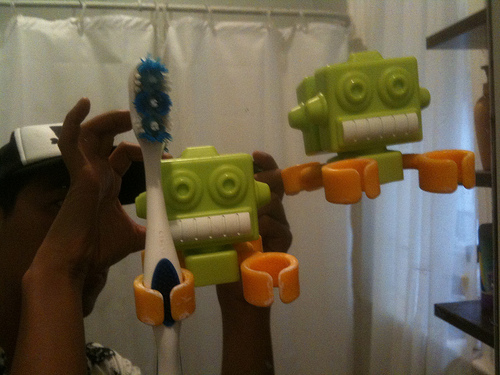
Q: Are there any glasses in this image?
A: No, there are no glasses.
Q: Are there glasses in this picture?
A: No, there are no glasses.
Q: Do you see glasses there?
A: No, there are no glasses.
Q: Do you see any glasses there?
A: No, there are no glasses.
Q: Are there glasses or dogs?
A: No, there are no glasses or dogs.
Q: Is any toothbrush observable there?
A: Yes, there is a toothbrush.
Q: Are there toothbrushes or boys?
A: Yes, there is a toothbrush.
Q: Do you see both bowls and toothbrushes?
A: No, there is a toothbrush but no bowls.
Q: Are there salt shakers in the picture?
A: No, there are no salt shakers.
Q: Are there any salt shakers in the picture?
A: No, there are no salt shakers.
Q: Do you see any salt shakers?
A: No, there are no salt shakers.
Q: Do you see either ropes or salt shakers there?
A: No, there are no salt shakers or ropes.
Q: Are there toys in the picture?
A: Yes, there is a toy.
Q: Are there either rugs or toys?
A: Yes, there is a toy.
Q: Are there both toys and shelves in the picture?
A: Yes, there are both a toy and a shelf.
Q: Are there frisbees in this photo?
A: No, there are no frisbees.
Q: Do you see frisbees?
A: No, there are no frisbees.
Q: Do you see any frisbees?
A: No, there are no frisbees.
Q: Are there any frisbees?
A: No, there are no frisbees.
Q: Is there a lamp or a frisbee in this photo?
A: No, there are no frisbees or lamps.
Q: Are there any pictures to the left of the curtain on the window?
A: No, there is a toy to the left of the curtain.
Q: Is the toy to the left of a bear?
A: No, the toy is to the left of the curtain.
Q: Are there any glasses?
A: No, there are no glasses.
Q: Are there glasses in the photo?
A: No, there are no glasses.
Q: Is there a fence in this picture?
A: No, there are no fences.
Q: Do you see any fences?
A: No, there are no fences.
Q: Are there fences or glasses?
A: No, there are no fences or glasses.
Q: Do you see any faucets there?
A: No, there are no faucets.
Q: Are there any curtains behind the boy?
A: Yes, there is a curtain behind the boy.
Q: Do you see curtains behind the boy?
A: Yes, there is a curtain behind the boy.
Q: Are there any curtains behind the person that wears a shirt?
A: Yes, there is a curtain behind the boy.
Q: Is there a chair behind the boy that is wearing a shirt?
A: No, there is a curtain behind the boy.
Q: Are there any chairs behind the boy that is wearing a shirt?
A: No, there is a curtain behind the boy.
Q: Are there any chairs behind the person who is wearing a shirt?
A: No, there is a curtain behind the boy.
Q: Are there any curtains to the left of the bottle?
A: Yes, there is a curtain to the left of the bottle.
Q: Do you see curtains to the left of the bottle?
A: Yes, there is a curtain to the left of the bottle.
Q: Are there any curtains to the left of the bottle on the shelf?
A: Yes, there is a curtain to the left of the bottle.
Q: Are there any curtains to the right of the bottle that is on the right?
A: No, the curtain is to the left of the bottle.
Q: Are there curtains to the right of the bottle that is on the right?
A: No, the curtain is to the left of the bottle.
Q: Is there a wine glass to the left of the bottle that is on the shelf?
A: No, there is a curtain to the left of the bottle.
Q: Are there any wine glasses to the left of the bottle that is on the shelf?
A: No, there is a curtain to the left of the bottle.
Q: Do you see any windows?
A: Yes, there is a window.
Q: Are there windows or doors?
A: Yes, there is a window.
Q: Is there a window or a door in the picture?
A: Yes, there is a window.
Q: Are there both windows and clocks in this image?
A: No, there is a window but no clocks.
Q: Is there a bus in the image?
A: No, there are no buses.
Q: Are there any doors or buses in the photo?
A: No, there are no buses or doors.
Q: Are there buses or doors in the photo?
A: No, there are no buses or doors.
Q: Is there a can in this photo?
A: Yes, there is a can.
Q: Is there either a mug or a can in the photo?
A: Yes, there is a can.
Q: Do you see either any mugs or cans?
A: Yes, there is a can.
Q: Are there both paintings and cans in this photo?
A: No, there is a can but no paintings.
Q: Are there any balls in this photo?
A: No, there are no balls.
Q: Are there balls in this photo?
A: No, there are no balls.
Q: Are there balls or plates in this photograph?
A: No, there are no balls or plates.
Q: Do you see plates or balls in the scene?
A: No, there are no balls or plates.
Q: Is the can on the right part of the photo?
A: Yes, the can is on the right of the image.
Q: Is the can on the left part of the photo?
A: No, the can is on the right of the image.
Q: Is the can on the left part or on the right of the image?
A: The can is on the right of the image.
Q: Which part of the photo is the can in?
A: The can is on the right of the image.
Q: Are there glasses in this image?
A: No, there are no glasses.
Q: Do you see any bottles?
A: Yes, there is a bottle.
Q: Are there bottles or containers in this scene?
A: Yes, there is a bottle.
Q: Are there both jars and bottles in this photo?
A: No, there is a bottle but no jars.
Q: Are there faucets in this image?
A: No, there are no faucets.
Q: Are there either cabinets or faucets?
A: No, there are no faucets or cabinets.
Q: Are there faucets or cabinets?
A: No, there are no faucets or cabinets.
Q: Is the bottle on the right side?
A: Yes, the bottle is on the right of the image.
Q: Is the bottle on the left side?
A: No, the bottle is on the right of the image.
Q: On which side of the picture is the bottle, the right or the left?
A: The bottle is on the right of the image.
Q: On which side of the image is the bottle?
A: The bottle is on the right of the image.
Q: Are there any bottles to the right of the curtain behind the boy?
A: Yes, there is a bottle to the right of the curtain.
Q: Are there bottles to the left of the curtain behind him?
A: No, the bottle is to the right of the curtain.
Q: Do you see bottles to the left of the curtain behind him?
A: No, the bottle is to the right of the curtain.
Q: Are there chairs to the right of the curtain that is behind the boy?
A: No, there is a bottle to the right of the curtain.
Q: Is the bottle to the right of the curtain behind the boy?
A: Yes, the bottle is to the right of the curtain.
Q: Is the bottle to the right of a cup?
A: No, the bottle is to the right of the curtain.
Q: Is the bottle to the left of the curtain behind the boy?
A: No, the bottle is to the right of the curtain.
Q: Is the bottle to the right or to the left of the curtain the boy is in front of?
A: The bottle is to the right of the curtain.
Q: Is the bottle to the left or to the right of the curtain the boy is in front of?
A: The bottle is to the right of the curtain.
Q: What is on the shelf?
A: The bottle is on the shelf.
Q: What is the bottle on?
A: The bottle is on the shelf.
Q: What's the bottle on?
A: The bottle is on the shelf.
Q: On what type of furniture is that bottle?
A: The bottle is on the shelf.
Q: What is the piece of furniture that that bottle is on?
A: The piece of furniture is a shelf.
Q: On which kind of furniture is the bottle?
A: The bottle is on the shelf.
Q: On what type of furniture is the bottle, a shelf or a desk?
A: The bottle is on a shelf.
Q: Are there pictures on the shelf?
A: No, there is a bottle on the shelf.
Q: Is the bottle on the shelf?
A: Yes, the bottle is on the shelf.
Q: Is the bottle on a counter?
A: No, the bottle is on the shelf.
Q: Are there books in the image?
A: No, there are no books.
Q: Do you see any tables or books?
A: No, there are no books or tables.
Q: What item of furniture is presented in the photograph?
A: The piece of furniture is a shelf.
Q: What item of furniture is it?
A: The piece of furniture is a shelf.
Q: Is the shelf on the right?
A: Yes, the shelf is on the right of the image.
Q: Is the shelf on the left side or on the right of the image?
A: The shelf is on the right of the image.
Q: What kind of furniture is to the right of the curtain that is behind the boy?
A: The piece of furniture is a shelf.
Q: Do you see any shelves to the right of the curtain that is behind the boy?
A: Yes, there is a shelf to the right of the curtain.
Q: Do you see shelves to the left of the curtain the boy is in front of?
A: No, the shelf is to the right of the curtain.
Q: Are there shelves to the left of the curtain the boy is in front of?
A: No, the shelf is to the right of the curtain.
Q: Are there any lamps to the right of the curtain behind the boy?
A: No, there is a shelf to the right of the curtain.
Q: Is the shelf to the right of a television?
A: No, the shelf is to the right of a curtain.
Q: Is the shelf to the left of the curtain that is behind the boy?
A: No, the shelf is to the right of the curtain.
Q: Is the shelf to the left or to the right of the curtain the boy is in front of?
A: The shelf is to the right of the curtain.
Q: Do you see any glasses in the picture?
A: No, there are no glasses.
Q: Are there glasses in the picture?
A: No, there are no glasses.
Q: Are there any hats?
A: Yes, there is a hat.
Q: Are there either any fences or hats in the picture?
A: Yes, there is a hat.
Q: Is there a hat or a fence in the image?
A: Yes, there is a hat.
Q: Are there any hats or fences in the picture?
A: Yes, there is a hat.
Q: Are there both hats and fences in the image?
A: No, there is a hat but no fences.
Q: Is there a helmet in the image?
A: No, there are no helmets.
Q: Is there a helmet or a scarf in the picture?
A: No, there are no helmets or scarves.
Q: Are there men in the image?
A: No, there are no men.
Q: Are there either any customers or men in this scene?
A: No, there are no men or customers.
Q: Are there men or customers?
A: No, there are no men or customers.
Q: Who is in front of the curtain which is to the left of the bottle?
A: The boy is in front of the curtain.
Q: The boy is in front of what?
A: The boy is in front of the curtain.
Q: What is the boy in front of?
A: The boy is in front of the curtain.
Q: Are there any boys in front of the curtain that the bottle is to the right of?
A: Yes, there is a boy in front of the curtain.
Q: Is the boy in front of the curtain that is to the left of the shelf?
A: Yes, the boy is in front of the curtain.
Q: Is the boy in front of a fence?
A: No, the boy is in front of the curtain.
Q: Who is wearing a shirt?
A: The boy is wearing a shirt.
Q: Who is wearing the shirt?
A: The boy is wearing a shirt.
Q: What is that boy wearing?
A: The boy is wearing a shirt.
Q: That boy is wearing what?
A: The boy is wearing a shirt.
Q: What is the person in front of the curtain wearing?
A: The boy is wearing a shirt.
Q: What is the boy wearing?
A: The boy is wearing a shirt.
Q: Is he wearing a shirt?
A: Yes, the boy is wearing a shirt.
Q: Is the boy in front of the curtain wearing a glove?
A: No, the boy is wearing a shirt.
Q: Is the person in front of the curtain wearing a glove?
A: No, the boy is wearing a shirt.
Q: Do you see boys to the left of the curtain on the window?
A: Yes, there is a boy to the left of the curtain.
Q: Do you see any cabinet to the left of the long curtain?
A: No, there is a boy to the left of the curtain.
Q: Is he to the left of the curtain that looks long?
A: Yes, the boy is to the left of the curtain.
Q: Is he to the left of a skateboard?
A: No, the boy is to the left of the curtain.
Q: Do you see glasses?
A: No, there are no glasses.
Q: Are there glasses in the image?
A: No, there are no glasses.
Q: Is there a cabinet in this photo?
A: No, there are no cabinets.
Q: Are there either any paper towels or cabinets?
A: No, there are no cabinets or paper towels.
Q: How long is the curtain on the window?
A: The curtain is long.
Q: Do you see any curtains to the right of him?
A: Yes, there is a curtain to the right of the boy.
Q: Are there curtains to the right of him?
A: Yes, there is a curtain to the right of the boy.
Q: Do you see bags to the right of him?
A: No, there is a curtain to the right of the boy.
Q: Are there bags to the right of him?
A: No, there is a curtain to the right of the boy.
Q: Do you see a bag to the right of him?
A: No, there is a curtain to the right of the boy.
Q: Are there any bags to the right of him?
A: No, there is a curtain to the right of the boy.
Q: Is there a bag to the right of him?
A: No, there is a curtain to the right of the boy.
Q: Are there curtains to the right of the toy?
A: Yes, there is a curtain to the right of the toy.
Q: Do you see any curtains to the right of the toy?
A: Yes, there is a curtain to the right of the toy.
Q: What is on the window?
A: The curtain is on the window.